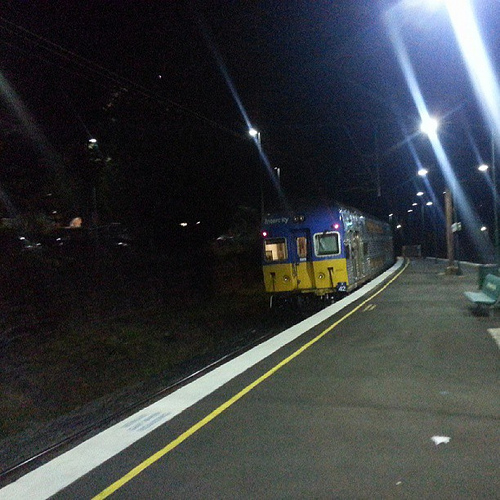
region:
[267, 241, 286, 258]
The left window of the train.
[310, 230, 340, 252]
The right window of the train.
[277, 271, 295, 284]
The left headlight on the train.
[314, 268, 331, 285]
The right headlight of the train.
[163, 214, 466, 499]
The yellow stripe on the platform.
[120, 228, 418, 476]
The white stripe on the platform.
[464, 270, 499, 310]
The green bench on the platform.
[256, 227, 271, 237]
The left light on the blue area of the train.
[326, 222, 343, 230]
The right light on the blue area of the train.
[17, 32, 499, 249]
The street lights in the area.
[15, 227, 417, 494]
The white line on the platform.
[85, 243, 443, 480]
The yellow line on the platform.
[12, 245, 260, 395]
The grass area to the left of the train.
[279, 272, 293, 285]
The left headlight in the yellow painted area of the train.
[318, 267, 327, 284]
The right headlight in the yellow area of the train.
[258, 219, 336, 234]
The two turned on headlights in the blue area of the train.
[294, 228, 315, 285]
The door between the two windows of the train.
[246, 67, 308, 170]
part of a the dark night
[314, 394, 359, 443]
part of a floor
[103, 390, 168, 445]
edge of a road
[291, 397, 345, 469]
part of a floor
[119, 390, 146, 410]
edge of a road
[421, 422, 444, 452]
part of a white substance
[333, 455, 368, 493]
part of a floor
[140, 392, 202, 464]
edge of a line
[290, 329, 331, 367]
Yellow stripe near train tracks.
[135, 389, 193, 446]
Thick white line on edge of platform.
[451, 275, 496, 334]
Green bench on train platform.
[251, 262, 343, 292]
Bottom section of train is yellow.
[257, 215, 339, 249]
Top section of train is blue.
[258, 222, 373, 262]
2 windows on back of train.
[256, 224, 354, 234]
Lights lite up on back of train.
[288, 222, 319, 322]
Narrow door on back of train.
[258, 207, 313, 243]
White writing on back of train.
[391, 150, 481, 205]
Lights on post on train platform.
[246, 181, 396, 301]
blue and yellow train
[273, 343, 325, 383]
yellow line on ground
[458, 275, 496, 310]
bench next to the train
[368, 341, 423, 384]
black ground next to bench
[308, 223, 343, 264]
front window on train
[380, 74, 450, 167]
light above the street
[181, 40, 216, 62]
black sky above ground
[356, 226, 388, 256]
side of the train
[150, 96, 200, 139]
wires above the ground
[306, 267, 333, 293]
light on front of the train